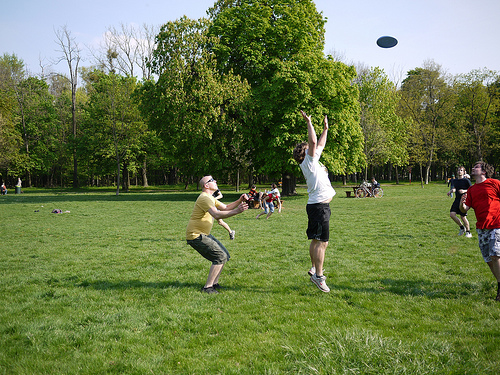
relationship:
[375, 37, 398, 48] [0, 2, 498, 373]
frisbee in air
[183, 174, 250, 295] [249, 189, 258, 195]
man with sunglasses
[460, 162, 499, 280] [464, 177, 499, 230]
man wearing shirt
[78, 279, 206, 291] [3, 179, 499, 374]
shadow on ground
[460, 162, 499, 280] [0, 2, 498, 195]
man looking up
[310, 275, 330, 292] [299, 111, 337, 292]
shoe of man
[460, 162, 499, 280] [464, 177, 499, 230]
man has on a shirt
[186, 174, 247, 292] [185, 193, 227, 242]
man has on a shirt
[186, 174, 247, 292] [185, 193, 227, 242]
man wearing shirt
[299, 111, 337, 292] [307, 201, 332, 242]
man wearing shorts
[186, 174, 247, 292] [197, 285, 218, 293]
man wearing shoe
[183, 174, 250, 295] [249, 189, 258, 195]
man wearing sunglasses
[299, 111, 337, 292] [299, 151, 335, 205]
man wearing shirt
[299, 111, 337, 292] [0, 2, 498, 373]
man jumping in air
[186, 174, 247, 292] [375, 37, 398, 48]
man ready to catch frisbee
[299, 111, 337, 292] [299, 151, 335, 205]
man with shirt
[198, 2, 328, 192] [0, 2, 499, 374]
tree in park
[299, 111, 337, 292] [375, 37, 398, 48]
man playing frisbee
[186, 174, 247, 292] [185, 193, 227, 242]
man wearing a yellow shirt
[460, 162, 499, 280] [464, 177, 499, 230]
man wearing a red shirt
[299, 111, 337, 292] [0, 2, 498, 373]
man jumping into air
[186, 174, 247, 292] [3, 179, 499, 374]
man standing in grass